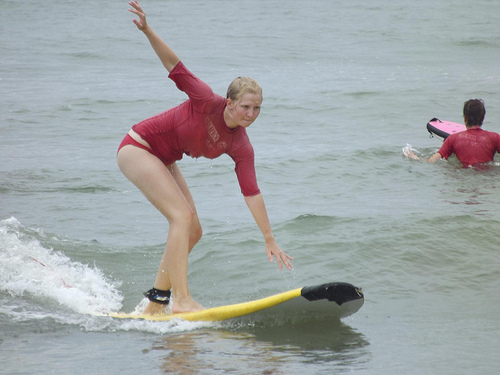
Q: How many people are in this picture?
A: Two.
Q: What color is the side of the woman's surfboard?
A: Yellow.